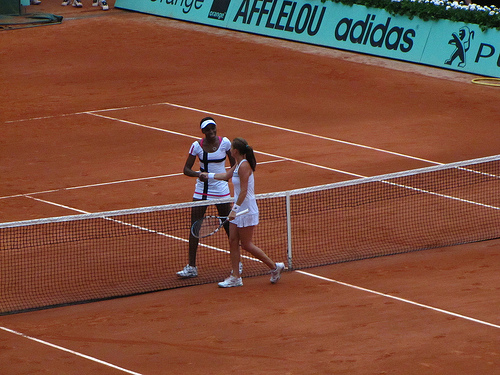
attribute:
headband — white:
[192, 117, 220, 132]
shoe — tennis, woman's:
[219, 272, 250, 289]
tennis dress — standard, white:
[188, 137, 234, 202]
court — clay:
[11, 14, 498, 372]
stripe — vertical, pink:
[201, 155, 213, 166]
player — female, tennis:
[197, 138, 284, 288]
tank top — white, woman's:
[214, 155, 276, 217]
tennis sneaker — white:
[174, 260, 201, 279]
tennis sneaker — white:
[229, 260, 247, 280]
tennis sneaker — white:
[215, 275, 242, 288]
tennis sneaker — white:
[270, 256, 287, 279]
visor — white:
[197, 119, 224, 134]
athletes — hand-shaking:
[176, 100, 296, 285]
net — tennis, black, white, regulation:
[1, 152, 498, 314]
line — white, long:
[18, 189, 497, 352]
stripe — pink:
[188, 144, 194, 156]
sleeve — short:
[186, 140, 200, 155]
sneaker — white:
[217, 274, 249, 289]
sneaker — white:
[264, 258, 286, 285]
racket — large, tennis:
[188, 207, 251, 241]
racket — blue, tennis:
[189, 208, 250, 237]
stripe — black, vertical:
[196, 146, 213, 205]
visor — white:
[198, 113, 240, 138]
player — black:
[160, 90, 235, 288]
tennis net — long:
[2, 152, 498, 322]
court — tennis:
[9, 17, 470, 357]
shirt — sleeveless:
[231, 160, 258, 211]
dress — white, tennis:
[214, 158, 276, 266]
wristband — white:
[199, 166, 219, 187]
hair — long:
[228, 140, 262, 174]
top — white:
[5, 155, 495, 227]